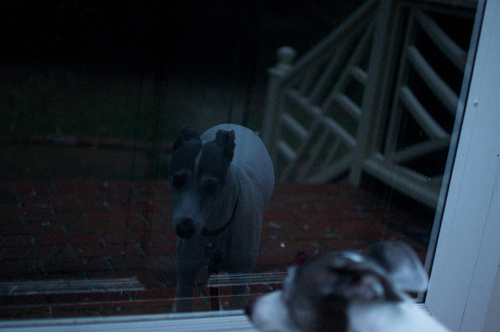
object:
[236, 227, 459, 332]
dog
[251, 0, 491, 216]
railing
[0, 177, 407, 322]
pavement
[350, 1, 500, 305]
door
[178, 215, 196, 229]
nose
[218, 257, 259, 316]
legs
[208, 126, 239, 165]
ears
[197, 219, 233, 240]
collar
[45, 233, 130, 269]
porch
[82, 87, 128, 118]
grass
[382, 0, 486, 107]
frame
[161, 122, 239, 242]
head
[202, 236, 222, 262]
tags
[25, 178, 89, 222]
floor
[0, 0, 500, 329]
reflection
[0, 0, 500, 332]
room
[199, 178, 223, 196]
eyes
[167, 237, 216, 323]
leg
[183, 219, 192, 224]
snout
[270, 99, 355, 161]
stairs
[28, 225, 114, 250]
brick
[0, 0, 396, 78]
wall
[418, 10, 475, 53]
pane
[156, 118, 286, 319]
reflection of dog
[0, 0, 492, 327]
window